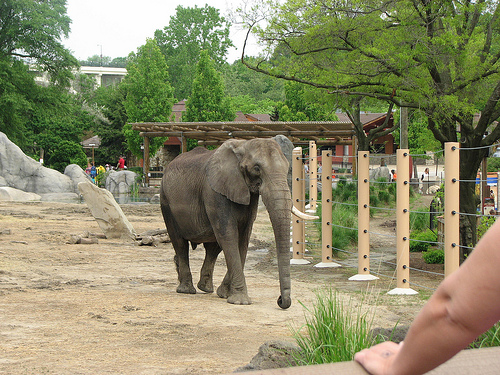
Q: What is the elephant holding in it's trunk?
A: A ball.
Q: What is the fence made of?
A: Wire.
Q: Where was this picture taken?
A: A zoo.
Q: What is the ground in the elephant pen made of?
A: Sand.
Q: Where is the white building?
A: Top left.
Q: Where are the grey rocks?
A: Middle left.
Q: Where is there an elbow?
A: Bottom right.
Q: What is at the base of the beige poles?
A: Cement.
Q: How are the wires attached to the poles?
A: Holes drilled thru wood.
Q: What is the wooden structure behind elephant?
A: Pagoda.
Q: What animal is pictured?
A: Elephant.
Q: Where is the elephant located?
A: Zoo.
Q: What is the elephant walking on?
A: Dirt.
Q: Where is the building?
A: Background.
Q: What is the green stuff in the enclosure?
A: Grass.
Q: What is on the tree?
A: Leaves.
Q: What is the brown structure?
A: Roof.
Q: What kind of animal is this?
A: An elephant.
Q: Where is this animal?
A: At a zoo.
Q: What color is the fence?
A: Tan.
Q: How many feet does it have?
A: Four.